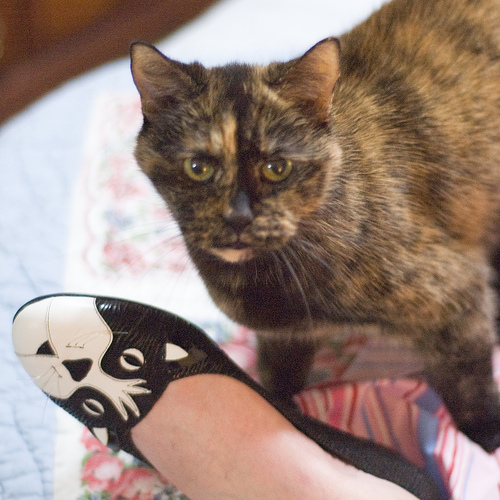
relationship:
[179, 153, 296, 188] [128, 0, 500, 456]
eyes of brown cat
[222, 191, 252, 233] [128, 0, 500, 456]
nose of brown cat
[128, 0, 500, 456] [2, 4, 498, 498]
brown cat standing on bed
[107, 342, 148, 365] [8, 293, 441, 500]
eye on black shoe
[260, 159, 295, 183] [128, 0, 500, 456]
eye on brown cat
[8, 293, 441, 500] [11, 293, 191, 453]
black shoe with cat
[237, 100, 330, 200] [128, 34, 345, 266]
fur on face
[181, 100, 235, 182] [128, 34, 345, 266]
fur on face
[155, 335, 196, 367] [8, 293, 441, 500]
ear on black shoe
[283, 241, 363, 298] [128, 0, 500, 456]
whiskers of brown cat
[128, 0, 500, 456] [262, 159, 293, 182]
brown cat has eye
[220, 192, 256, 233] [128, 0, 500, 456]
nose of brown cat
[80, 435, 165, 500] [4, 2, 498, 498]
flowers in blanket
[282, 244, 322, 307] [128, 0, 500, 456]
whisker on brown cat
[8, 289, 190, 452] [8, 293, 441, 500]
cat printed on black shoe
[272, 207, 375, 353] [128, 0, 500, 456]
whiskers of brown cat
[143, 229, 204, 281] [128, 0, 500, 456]
whiskers of brown cat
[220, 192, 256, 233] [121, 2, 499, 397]
nose of cat